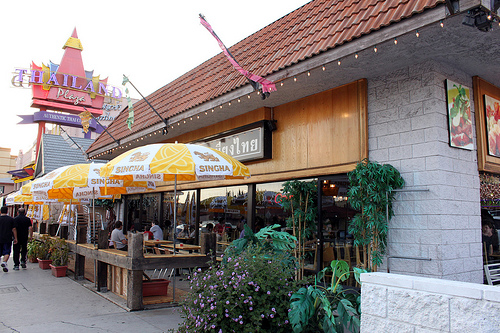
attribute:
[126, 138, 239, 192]
umbrella — yellow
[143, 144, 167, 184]
umbrella — yellow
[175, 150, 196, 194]
umbrella — yellow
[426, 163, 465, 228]
wall — brick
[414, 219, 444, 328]
wall — brick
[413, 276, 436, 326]
wall — brick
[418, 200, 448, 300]
wall — brick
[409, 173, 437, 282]
wall — brick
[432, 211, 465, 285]
wall — brick